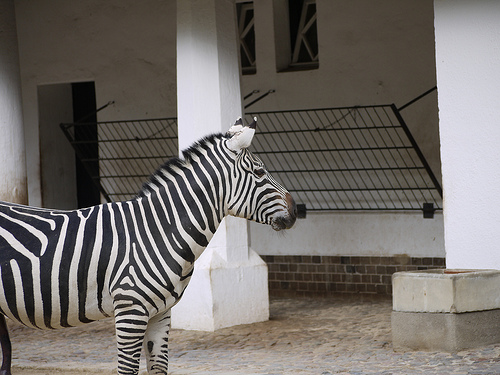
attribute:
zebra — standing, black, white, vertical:
[3, 110, 309, 375]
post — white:
[426, 1, 499, 271]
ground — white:
[14, 327, 499, 372]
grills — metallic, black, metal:
[60, 89, 451, 227]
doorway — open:
[33, 73, 106, 208]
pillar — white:
[163, 1, 272, 336]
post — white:
[1, 1, 32, 203]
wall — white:
[16, 9, 443, 267]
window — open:
[269, 1, 326, 79]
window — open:
[235, 2, 262, 79]